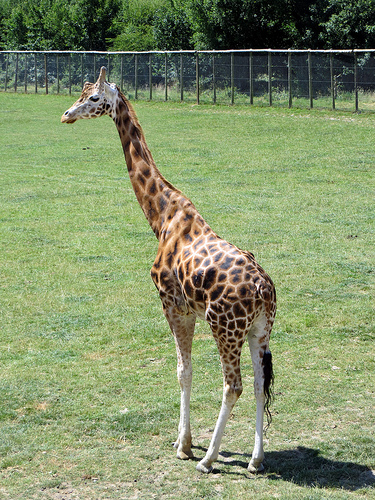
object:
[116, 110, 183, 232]
neck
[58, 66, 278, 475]
giraffe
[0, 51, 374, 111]
fence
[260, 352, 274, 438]
hair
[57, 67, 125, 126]
head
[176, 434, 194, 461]
foot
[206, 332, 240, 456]
leg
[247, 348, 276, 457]
leg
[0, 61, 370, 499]
area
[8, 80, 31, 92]
wheel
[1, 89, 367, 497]
ground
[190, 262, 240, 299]
patches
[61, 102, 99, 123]
muzzle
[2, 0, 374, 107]
background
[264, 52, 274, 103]
pole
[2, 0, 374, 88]
trees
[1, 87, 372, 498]
grass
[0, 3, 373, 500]
photo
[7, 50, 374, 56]
bar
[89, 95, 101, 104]
eye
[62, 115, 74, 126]
mouth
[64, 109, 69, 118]
nose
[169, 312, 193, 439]
legs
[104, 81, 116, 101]
ear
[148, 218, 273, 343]
body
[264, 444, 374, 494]
shadow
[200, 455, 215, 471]
hooves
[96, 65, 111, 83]
horns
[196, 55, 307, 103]
posts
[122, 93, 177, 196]
mane